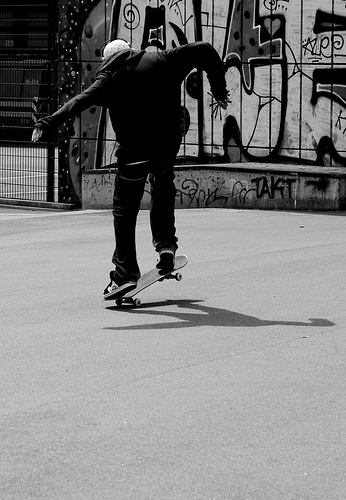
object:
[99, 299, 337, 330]
shadow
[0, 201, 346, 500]
ground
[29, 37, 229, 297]
man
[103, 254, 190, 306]
board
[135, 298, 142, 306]
wheels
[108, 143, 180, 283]
pants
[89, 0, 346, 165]
graffiti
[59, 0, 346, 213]
wall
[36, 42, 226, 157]
shirt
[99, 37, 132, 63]
headphones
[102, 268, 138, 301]
shoes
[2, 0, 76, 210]
fence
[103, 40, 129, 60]
hat